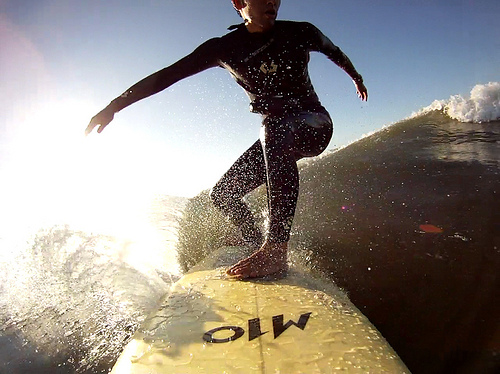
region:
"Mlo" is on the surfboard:
[163, 270, 328, 348]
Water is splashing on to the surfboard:
[6, 86, 247, 347]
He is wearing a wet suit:
[89, 4, 394, 284]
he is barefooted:
[188, 191, 309, 278]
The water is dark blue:
[316, 65, 493, 297]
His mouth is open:
[239, 5, 307, 40]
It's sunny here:
[17, 12, 464, 173]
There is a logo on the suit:
[233, 37, 305, 112]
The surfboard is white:
[159, 195, 391, 363]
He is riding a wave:
[5, 72, 499, 276]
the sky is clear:
[58, 16, 206, 91]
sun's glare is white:
[10, 4, 150, 216]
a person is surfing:
[88, 9, 380, 369]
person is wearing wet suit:
[125, 15, 396, 260]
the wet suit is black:
[101, 12, 376, 271]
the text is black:
[170, 235, 357, 365]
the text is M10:
[200, 297, 341, 362]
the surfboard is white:
[146, 227, 409, 372]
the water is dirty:
[285, 177, 475, 279]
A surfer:
[110, 138, 308, 323]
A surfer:
[192, 177, 296, 359]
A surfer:
[187, 94, 294, 255]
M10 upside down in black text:
[190, 296, 328, 354]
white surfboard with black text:
[140, 242, 392, 367]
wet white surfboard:
[142, 245, 316, 363]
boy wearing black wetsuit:
[137, 1, 371, 337]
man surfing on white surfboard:
[144, 2, 368, 344]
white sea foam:
[14, 207, 192, 365]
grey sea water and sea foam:
[415, 80, 488, 130]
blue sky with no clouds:
[372, 12, 489, 74]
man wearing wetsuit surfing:
[155, 3, 330, 319]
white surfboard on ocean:
[116, 224, 321, 359]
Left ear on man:
[228, 1, 250, 11]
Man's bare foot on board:
[223, 241, 287, 289]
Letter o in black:
[193, 307, 245, 359]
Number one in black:
[243, 310, 270, 353]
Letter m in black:
[268, 305, 315, 342]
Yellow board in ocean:
[108, 253, 413, 371]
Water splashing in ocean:
[15, 216, 150, 340]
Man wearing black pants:
[205, 108, 347, 243]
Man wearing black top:
[202, 30, 341, 107]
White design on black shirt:
[233, 40, 302, 86]